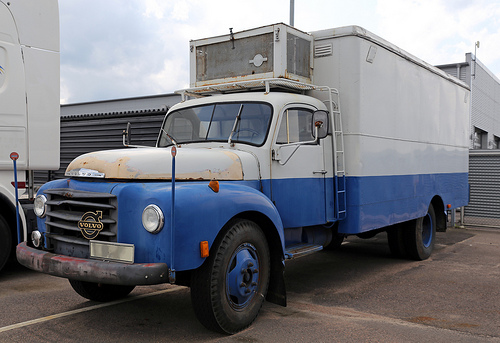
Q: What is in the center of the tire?
A: A blue hubcap.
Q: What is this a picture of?
A: Refrigeration system.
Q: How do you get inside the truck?
A: Blue and white door.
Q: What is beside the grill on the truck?
A: Two headlights.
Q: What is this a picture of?
A: Blue and white truck.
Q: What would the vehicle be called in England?
A: A Lorry.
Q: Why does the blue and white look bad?
A: It is from another era.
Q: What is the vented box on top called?
A: A refrigeration unit.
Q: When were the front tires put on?
A: Not recently.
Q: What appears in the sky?
A: Gray and white clouds.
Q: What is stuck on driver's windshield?
A: Windshield wiper.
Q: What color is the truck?
A: Gray and blue.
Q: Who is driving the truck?
A: A man.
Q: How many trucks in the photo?
A: One.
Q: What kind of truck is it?
A: Volvo.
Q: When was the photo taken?
A: Daytime.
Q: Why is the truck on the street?
A: Parked.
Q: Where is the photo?
A: The street.